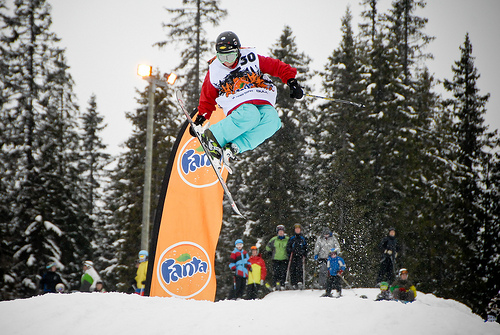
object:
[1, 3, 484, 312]
background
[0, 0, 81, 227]
tree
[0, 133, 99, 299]
tree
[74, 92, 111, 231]
tree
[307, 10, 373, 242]
tree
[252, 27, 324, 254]
tree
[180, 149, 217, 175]
word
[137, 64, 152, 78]
light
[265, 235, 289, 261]
coat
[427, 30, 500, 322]
tree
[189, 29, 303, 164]
person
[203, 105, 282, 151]
pants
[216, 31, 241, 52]
helmet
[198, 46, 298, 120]
shirt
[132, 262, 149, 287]
jacket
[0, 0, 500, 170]
sky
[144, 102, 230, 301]
banner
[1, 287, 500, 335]
slope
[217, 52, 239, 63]
goggles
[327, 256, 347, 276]
jacket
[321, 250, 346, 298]
spectator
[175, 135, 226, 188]
circle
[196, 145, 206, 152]
leaf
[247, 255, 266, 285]
jacket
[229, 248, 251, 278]
coat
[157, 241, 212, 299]
logo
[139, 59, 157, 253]
post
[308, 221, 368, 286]
snow